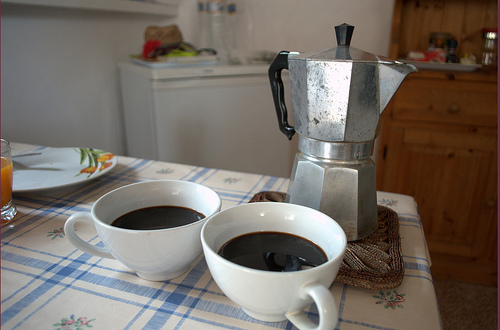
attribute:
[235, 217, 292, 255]
liquid — brown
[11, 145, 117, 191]
plate — white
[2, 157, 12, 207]
juice — orange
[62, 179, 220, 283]
mug — white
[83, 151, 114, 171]
flower — orange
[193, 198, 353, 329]
coffee cup — coffee 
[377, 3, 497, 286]
cabinet — blurry, wooden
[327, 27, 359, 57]
top — black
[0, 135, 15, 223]
glass — juice 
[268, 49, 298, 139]
handle — black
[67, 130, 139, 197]
flowers — yellow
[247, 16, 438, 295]
coffee pot — metallic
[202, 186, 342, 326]
coffee cup — coffee 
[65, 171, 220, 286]
cup — coffee , white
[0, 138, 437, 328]
tablecloth — blue, checkered, white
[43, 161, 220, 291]
cup — coffee cup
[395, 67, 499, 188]
cabinet — wooden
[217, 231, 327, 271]
liquid — brown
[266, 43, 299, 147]
handle — black 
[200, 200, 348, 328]
cup — coffee cup, white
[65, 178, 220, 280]
cup — coffee cup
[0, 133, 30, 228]
drinking glass — clear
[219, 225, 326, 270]
coffee — very dark 